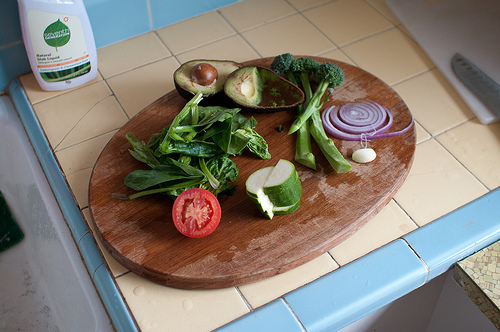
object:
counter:
[15, 2, 498, 327]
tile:
[326, 199, 422, 266]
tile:
[387, 65, 472, 138]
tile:
[31, 81, 130, 151]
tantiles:
[348, 24, 457, 197]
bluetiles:
[274, 193, 499, 318]